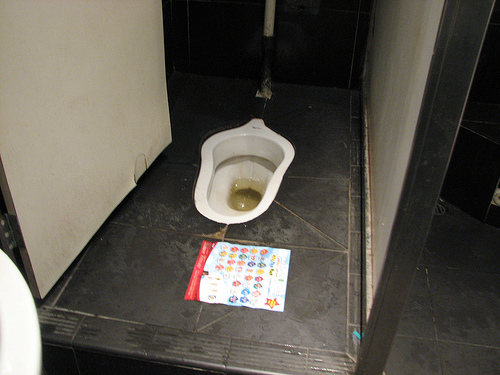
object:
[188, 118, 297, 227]
toilet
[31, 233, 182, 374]
floor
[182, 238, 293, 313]
paper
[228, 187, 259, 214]
water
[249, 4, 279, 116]
tube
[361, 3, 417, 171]
wall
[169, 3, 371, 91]
wall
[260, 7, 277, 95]
pipe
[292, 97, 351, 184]
tile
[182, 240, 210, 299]
page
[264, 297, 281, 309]
star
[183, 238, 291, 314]
sticker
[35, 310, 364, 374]
ground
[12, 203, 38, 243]
hinges